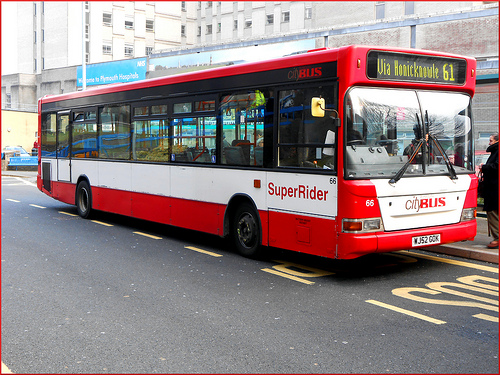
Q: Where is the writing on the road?
A: Under the bus.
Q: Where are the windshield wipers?
A: On the front window.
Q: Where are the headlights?
A: On the front of the bus.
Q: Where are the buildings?
A: Behind the bus.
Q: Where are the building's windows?
A: Above the bus.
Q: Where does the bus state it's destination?
A: Above the windshield.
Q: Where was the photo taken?
A: City street.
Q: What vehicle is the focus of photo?
A: Bus.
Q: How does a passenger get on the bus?
A: Front door.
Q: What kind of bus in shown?
A: Passenger.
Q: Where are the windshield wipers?
A: Front windows.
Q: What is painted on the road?
A: Yellow lines.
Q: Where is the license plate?
A: Bottom front.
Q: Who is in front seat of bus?
A: Driver.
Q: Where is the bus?
A: On road.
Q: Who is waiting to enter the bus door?
A: Female.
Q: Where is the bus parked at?
A: Bus stop.